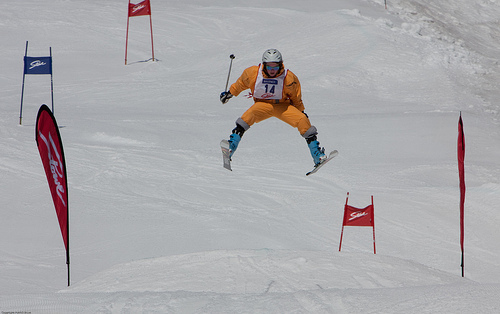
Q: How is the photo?
A: Clear.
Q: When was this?
A: Daytime.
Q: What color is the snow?
A: White.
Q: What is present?
A: A man.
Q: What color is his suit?
A: Yellow.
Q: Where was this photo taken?
A: On the snow.